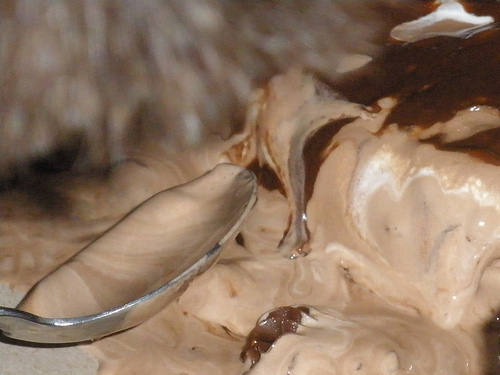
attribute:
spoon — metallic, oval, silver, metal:
[0, 162, 268, 346]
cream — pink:
[90, 14, 500, 374]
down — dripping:
[259, 81, 388, 290]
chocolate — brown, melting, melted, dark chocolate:
[332, 35, 496, 142]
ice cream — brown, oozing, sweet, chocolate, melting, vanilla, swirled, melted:
[277, 37, 499, 372]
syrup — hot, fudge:
[289, 21, 499, 251]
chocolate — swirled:
[208, 91, 374, 266]